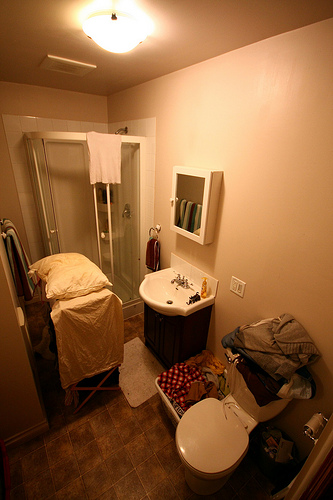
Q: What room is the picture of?
A: A bathroom.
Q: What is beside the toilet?
A: A basket of clothes.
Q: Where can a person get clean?
A: In the shower.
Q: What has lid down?
A: Toilet.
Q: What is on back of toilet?
A: Clothes.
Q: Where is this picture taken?
A: Bathroom.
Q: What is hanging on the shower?
A: Towel.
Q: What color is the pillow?
A: Yellow.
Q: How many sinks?
A: One.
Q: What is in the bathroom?
A: Laundry.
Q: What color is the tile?
A: Brown.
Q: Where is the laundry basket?
A: By the toilet.